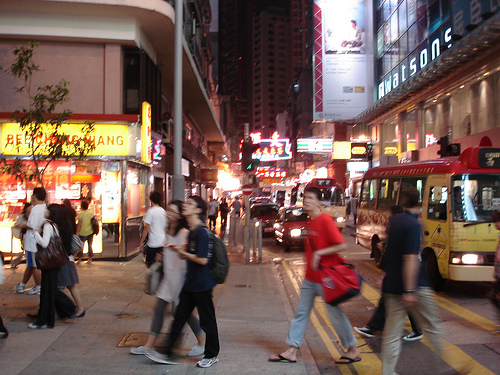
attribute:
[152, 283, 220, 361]
black pants — gray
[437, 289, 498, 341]
line — yellow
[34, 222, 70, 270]
bag — big, brown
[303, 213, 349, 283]
shirt — red 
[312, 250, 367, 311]
bag — red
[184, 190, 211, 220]
hair — black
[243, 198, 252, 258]
post — gray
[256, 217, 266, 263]
post — gray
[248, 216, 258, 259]
post — gray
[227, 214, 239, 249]
post — gray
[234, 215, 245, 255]
post — gray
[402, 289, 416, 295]
watch — black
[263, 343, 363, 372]
slippers — black, a pair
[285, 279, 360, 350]
pants — grey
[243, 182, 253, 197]
sign — stop, on pole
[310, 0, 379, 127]
billboard — big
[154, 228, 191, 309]
shirt — white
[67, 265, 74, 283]
skirt — grey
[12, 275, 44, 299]
shoes — white, rubber, a pair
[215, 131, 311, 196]
sign — small, road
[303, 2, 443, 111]
light — green, on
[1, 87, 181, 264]
light — green, on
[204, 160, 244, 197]
light — green, on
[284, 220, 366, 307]
bag — red with blue base